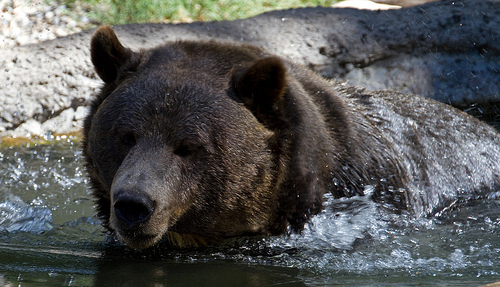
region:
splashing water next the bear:
[268, 186, 486, 281]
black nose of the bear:
[101, 183, 160, 225]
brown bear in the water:
[66, 33, 483, 252]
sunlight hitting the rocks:
[1, 1, 94, 161]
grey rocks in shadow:
[290, 4, 492, 85]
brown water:
[9, 146, 93, 260]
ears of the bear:
[76, 29, 301, 131]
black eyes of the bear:
[111, 113, 221, 175]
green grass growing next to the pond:
[48, 0, 315, 25]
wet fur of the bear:
[310, 62, 487, 231]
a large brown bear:
[53, 8, 495, 244]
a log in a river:
[203, 1, 491, 103]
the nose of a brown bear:
[97, 146, 179, 242]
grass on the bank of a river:
[97, 0, 259, 20]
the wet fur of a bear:
[353, 67, 471, 204]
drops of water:
[6, 135, 73, 189]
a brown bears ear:
[215, 41, 303, 123]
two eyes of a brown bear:
[91, 123, 205, 165]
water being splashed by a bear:
[297, 176, 473, 274]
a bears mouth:
[101, 222, 171, 248]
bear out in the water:
[17, 12, 484, 279]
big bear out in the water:
[10, 16, 464, 274]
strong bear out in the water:
[24, 15, 489, 270]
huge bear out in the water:
[17, 19, 474, 261]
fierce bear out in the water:
[8, 13, 478, 270]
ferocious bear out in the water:
[27, 18, 467, 268]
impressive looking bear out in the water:
[26, 8, 463, 265]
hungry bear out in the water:
[24, 3, 466, 274]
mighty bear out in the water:
[22, 21, 474, 265]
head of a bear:
[55, 22, 291, 254]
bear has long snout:
[111, 160, 192, 247]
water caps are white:
[307, 200, 397, 251]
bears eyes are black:
[107, 126, 203, 158]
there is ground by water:
[6, 136, 86, 152]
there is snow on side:
[10, 27, 76, 123]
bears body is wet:
[378, 80, 498, 200]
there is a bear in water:
[68, 38, 489, 255]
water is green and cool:
[15, 255, 246, 282]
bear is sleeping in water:
[107, 125, 207, 165]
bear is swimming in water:
[35, 29, 493, 256]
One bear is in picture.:
[83, 54, 486, 242]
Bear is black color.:
[146, 66, 368, 193]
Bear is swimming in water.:
[172, 143, 422, 285]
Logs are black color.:
[236, 20, 480, 91]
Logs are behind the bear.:
[289, 21, 488, 106]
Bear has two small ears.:
[86, 22, 294, 107]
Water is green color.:
[22, 220, 114, 280]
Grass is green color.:
[107, 6, 248, 25]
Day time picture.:
[7, 14, 472, 264]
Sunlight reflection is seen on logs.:
[12, 19, 361, 96]